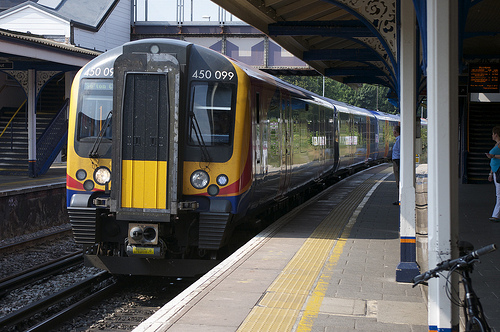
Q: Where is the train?
A: At the train station.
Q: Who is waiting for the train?
A: Passengers.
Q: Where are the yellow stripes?
A: On the ground.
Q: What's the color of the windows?
A: Transparent.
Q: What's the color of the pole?
A: White.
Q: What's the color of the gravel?
A: Grey.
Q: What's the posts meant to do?
A: Support.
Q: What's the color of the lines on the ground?
A: Yellow.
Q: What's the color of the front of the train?
A: Yellow.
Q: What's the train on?
A: Tracks.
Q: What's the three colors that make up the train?
A: Red,yellow and blue.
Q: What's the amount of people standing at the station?
A: Two.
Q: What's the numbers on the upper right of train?
A: 450 099.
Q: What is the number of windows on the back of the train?
A: Two.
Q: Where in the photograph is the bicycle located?
A: The foreground.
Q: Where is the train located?
A: On tracks.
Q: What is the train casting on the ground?
A: A shadow.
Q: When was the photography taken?
A: During daylight.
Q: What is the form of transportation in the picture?
A: Train.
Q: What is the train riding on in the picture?
A: Tracks.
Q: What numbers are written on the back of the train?
A: 450 099.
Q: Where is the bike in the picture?
A: Next to building.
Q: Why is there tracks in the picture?
A: For the train.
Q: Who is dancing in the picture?
A: No one.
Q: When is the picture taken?
A: Daytime.